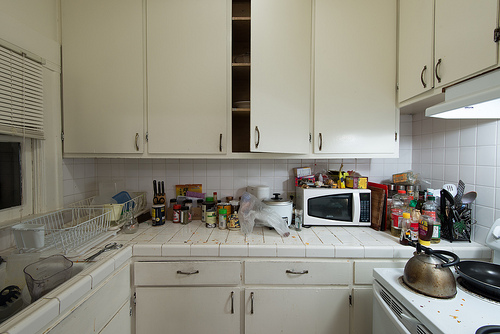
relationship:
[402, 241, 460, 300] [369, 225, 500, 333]
teapot on stove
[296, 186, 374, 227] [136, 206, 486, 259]
microwave on counter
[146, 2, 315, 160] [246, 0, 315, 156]
cabinet has door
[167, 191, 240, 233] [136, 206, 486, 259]
jars on counter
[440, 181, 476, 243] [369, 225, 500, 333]
utensils beside stove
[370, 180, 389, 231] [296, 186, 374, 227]
cutting board next to microwave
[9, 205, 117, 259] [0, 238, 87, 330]
dish drainer next to sink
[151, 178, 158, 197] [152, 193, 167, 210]
knife in knife block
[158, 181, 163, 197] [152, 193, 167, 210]
knife in knife block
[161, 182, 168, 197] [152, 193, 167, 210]
knife in knife block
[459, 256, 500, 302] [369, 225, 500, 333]
pan on stove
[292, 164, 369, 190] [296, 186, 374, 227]
stuff on microwave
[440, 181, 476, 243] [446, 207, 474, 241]
utensils are in caddy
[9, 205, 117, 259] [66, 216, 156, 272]
dish dryer on counter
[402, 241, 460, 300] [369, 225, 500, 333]
teakettle on stove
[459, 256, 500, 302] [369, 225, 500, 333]
frying pan on stove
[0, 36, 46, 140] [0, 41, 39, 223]
blinds on window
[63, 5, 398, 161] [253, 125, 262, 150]
cupboards have handles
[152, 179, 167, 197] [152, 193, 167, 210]
knives in block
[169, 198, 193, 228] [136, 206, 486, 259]
spices on counter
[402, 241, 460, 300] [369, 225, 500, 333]
tea kettle on stove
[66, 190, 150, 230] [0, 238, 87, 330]
dish rack next to sink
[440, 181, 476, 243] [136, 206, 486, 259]
utensils are on counter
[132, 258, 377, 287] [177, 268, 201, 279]
drawer has handle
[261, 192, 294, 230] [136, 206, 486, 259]
rice cooker on counter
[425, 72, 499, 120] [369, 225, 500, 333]
light above stove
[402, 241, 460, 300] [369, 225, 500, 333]
kettle on stove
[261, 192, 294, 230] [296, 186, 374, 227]
pressure cooker next to microwave